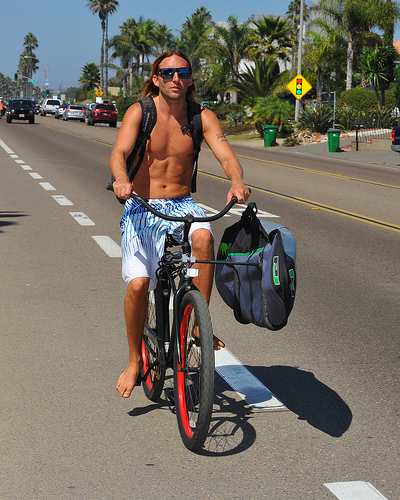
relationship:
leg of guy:
[116, 208, 158, 406] [107, 49, 249, 398]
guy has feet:
[107, 49, 249, 398] [93, 308, 253, 415]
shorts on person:
[121, 191, 210, 277] [64, 46, 253, 395]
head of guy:
[152, 50, 195, 100] [109, 49, 250, 399]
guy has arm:
[107, 49, 249, 398] [110, 101, 139, 198]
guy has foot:
[107, 49, 249, 398] [114, 359, 143, 397]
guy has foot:
[107, 49, 249, 398] [192, 324, 225, 351]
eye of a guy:
[160, 64, 174, 81] [107, 49, 249, 398]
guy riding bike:
[107, 49, 249, 398] [101, 176, 255, 455]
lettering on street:
[187, 191, 280, 227] [1, 219, 106, 495]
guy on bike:
[109, 49, 250, 399] [101, 176, 255, 455]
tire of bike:
[164, 288, 219, 457] [101, 176, 255, 455]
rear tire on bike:
[142, 336, 164, 396] [116, 176, 237, 454]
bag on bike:
[213, 211, 307, 345] [141, 205, 230, 470]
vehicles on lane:
[2, 91, 116, 129] [4, 169, 347, 494]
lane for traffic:
[4, 118, 398, 494] [0, 90, 42, 123]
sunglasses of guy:
[155, 65, 191, 78] [109, 49, 250, 399]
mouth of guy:
[171, 85, 178, 90] [107, 49, 249, 398]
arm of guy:
[200, 111, 242, 183] [109, 49, 250, 399]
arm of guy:
[108, 99, 142, 198] [109, 49, 250, 399]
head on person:
[150, 50, 195, 99] [108, 39, 262, 420]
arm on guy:
[200, 112, 245, 184] [107, 49, 249, 398]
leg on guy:
[191, 229, 214, 323] [107, 49, 249, 398]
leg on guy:
[170, 209, 215, 323] [107, 49, 249, 398]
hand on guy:
[104, 175, 145, 204] [107, 49, 249, 398]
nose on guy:
[169, 73, 182, 86] [107, 49, 249, 398]